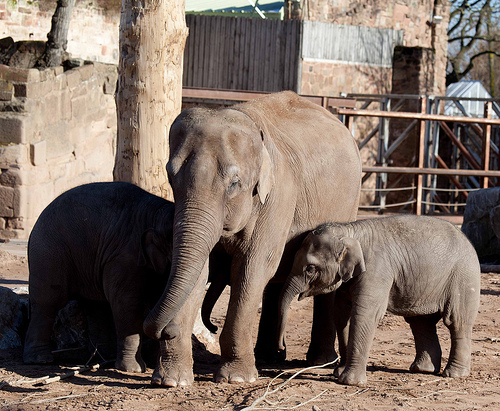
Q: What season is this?
A: Winter.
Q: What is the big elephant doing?
A: Looking at the camera.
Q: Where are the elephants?
A: In a zoo.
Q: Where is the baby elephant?
A: Next to the mother.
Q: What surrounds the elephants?
A: A fence.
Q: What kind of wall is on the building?
A: Bricks and stones.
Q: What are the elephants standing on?
A: Dirt ground.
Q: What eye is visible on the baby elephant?
A: Left eye.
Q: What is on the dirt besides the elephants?
A: Twigs and branches.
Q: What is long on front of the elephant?
A: Trunk.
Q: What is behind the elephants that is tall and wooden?
A: A tree trunk.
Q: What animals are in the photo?
A: Three elephants.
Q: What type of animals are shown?
A: Elephants.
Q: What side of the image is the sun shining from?
A: Right.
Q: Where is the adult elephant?
A: Middle.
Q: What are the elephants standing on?
A: Dirt.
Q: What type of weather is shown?
A: Clear and sunny.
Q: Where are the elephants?
A: Inside a fenced lot.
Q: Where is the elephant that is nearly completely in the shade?
A: Left side.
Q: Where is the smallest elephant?
A: Right side.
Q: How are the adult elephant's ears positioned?
A: Laid back.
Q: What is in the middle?
A: A large trunk of big elephant.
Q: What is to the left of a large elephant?
A: A very dark elephant.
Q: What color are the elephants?
A: Gray.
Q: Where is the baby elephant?
A: Next to the adult elephant.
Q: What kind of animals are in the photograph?
A: Elephants.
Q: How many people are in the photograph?
A: Zero.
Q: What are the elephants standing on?
A: Dirt.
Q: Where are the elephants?
A: In a pen.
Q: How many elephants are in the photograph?
A: Two.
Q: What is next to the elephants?
A: A tree.